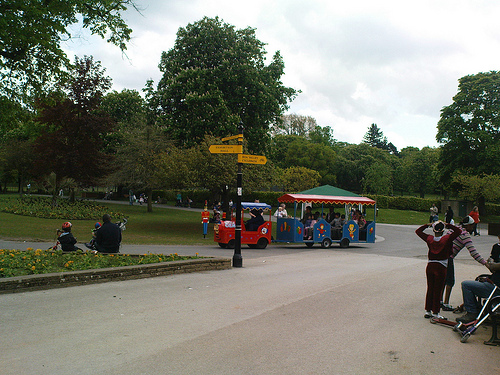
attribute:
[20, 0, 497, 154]
sky — cloud-filled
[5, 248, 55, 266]
flowers — Yellow 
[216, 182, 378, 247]
trolley — behind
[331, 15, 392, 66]
sky — white, grey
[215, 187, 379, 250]
train — brightly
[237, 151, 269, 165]
sign — yellow , black 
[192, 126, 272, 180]
signs — yellow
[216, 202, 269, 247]
train — small and red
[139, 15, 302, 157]
tree — large, leafy, green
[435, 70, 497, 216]
tree — green, leafy, large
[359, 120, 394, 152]
tree — green, leafy, large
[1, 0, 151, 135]
tree — green, leafy, large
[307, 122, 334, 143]
tree — green, leafy, large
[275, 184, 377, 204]
colored awning — brightly colored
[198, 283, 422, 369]
sidewalk — light brown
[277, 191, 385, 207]
roof — blue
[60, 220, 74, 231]
helmet — red 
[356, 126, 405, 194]
tree — tall , green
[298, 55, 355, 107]
cloud — heavy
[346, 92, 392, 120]
cloud — heavy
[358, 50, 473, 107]
cloud — heavy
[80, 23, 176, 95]
cloud — heavy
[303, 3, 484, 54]
cloud — heavy